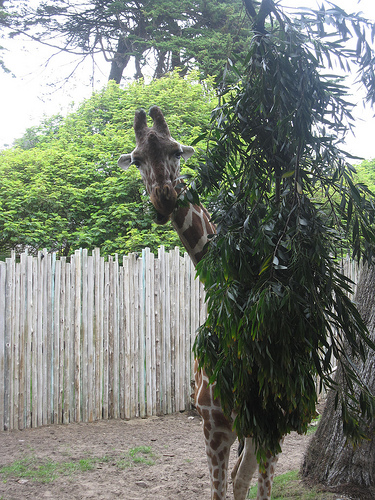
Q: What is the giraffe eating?
A: Leaves.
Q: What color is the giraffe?
A: Brown and tan.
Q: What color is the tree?
A: Green.